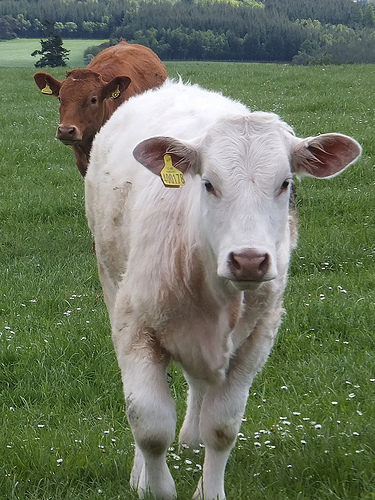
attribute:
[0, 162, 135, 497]
grass — green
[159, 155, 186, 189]
tag — yellow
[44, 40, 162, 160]
cow — brown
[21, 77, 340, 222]
cow — white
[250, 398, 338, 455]
flowers — white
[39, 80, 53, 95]
tag — yellow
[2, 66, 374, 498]
plants — wild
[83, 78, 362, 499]
cow — white